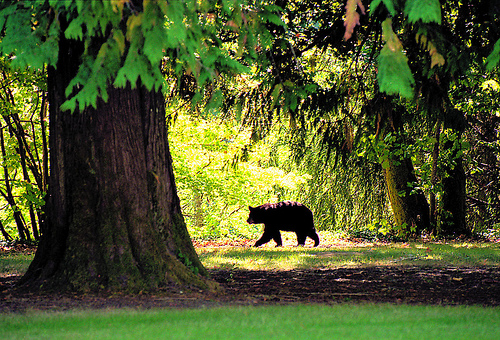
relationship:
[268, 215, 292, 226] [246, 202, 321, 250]
black on bear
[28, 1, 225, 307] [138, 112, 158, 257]
tree very giant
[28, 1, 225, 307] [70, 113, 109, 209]
tree has bark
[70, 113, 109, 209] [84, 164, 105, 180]
bark has moss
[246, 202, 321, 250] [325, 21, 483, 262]
bear in woods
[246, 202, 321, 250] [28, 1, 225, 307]
bear under a tree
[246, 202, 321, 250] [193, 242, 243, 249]
bear needs food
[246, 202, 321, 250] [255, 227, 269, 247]
bear on guard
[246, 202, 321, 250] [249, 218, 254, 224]
bear has teeth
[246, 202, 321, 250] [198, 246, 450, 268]
bear on ground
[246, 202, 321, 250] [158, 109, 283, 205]
bear likes day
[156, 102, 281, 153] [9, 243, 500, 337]
sun in park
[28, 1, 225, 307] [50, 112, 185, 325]
tree has a trunk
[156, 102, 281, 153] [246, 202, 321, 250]
sun on bear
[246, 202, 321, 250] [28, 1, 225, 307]
bear near a tree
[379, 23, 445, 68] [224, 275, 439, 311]
leaves are in shade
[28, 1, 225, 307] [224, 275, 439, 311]
tree gives shade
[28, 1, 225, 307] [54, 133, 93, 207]
tree has an indentation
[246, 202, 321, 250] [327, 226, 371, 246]
bear near leaves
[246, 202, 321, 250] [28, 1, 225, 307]
bear near tree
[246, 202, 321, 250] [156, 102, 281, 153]
bear in sun